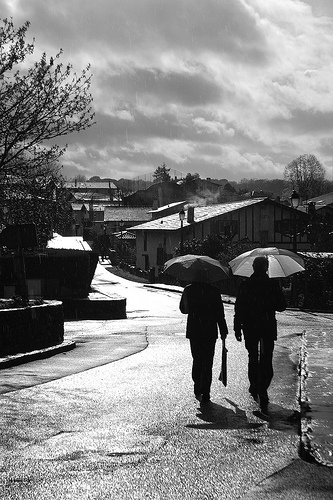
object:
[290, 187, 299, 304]
street lamp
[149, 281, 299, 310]
sidewalk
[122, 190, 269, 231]
roof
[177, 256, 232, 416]
people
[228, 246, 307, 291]
umbrella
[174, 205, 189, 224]
street light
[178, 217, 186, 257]
pole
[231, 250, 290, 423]
person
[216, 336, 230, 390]
bag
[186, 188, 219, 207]
smoke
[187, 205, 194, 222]
chimney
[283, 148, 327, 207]
tree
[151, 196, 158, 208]
chimney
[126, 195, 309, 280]
building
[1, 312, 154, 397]
curb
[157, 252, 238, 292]
umbrellas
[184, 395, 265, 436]
shadow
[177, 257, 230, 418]
person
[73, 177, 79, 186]
chimney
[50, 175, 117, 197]
building